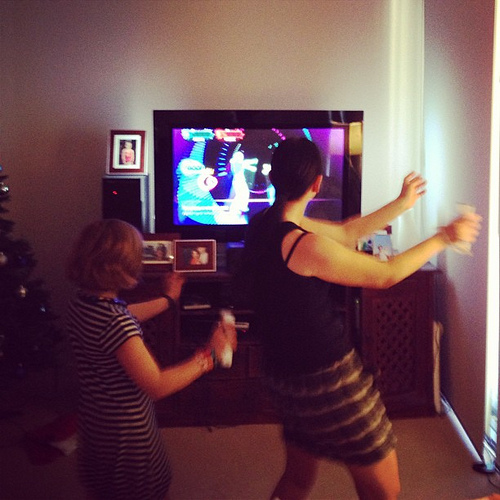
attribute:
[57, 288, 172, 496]
striped dress — striped 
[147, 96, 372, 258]
television — flatscreen 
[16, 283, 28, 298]
ornament — Christmas, ball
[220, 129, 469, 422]
woman — adult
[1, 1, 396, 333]
wall — white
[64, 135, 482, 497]
people — playing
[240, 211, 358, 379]
shirt — black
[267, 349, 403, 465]
skirt — striped 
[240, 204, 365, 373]
top — black 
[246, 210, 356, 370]
tank top — black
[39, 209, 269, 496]
girl — young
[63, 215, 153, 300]
hair — brown colored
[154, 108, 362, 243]
television — flat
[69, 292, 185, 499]
girl — young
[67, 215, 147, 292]
light hair — short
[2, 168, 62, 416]
tree — unlit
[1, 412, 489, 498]
beige carpet — beige 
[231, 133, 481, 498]
person — playing, standing up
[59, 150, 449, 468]
women — young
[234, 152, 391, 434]
person — standing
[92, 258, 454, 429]
media center — brown, wooden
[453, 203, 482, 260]
controller — white